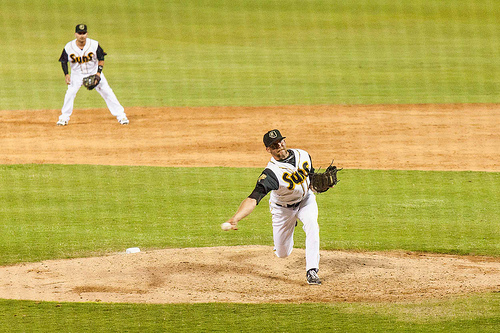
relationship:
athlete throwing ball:
[223, 129, 319, 284] [123, 242, 143, 257]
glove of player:
[307, 161, 342, 193] [223, 123, 353, 292]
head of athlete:
[261, 127, 289, 158] [223, 129, 319, 284]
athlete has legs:
[223, 129, 319, 284] [60, 79, 133, 133]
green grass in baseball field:
[1, 0, 500, 111] [0, 0, 500, 333]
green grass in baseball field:
[0, 162, 499, 269] [0, 0, 500, 333]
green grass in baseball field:
[0, 293, 500, 333] [0, 0, 500, 333]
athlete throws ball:
[223, 129, 319, 284] [195, 200, 273, 252]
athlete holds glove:
[223, 129, 319, 284] [310, 160, 344, 193]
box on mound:
[91, 205, 196, 302] [4, 232, 498, 318]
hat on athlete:
[258, 126, 305, 148] [223, 129, 319, 284]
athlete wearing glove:
[223, 129, 319, 284] [308, 162, 340, 202]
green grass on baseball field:
[1, 3, 499, 107] [0, 0, 500, 327]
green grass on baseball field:
[1, 162, 498, 257] [0, 0, 500, 327]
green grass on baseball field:
[1, 293, 499, 331] [0, 0, 500, 327]